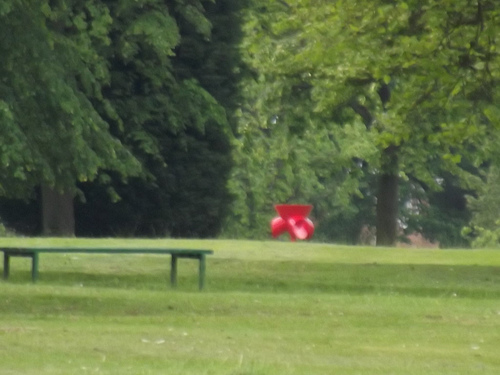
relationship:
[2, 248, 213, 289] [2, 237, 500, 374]
bench on grass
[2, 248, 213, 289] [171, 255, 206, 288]
bench has legs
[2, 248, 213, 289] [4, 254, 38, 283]
bench has legs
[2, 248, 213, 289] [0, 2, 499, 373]
bench in a field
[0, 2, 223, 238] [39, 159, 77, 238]
tree has a trunk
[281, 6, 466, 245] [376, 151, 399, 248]
tree has a trunk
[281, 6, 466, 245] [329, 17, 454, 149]
tree has leaves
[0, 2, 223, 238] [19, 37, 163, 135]
tree has leaves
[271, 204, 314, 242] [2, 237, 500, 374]
object on grass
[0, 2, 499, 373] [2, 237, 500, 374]
field full of grass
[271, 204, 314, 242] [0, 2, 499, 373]
object in field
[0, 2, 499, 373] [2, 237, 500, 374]
field has grass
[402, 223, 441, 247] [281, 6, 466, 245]
building behind tree